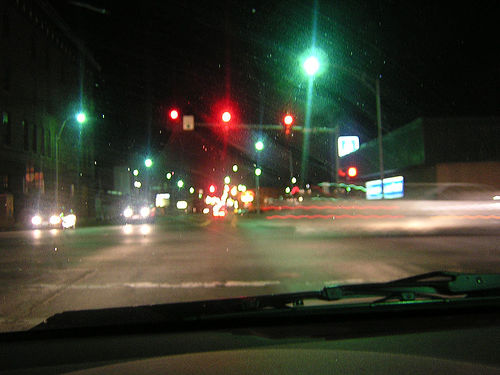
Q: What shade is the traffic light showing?
A: Red.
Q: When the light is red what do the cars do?
A: Stop.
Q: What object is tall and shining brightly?
A: Lamp post.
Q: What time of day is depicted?
A: Night.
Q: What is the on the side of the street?
A: A building.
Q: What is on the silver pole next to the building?
A: Streetlight.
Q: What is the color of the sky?
A: Black.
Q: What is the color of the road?
A: Grey.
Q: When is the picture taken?
A: Night time.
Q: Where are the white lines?
A: In the road.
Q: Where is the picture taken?
A: Inside a car, on the road.